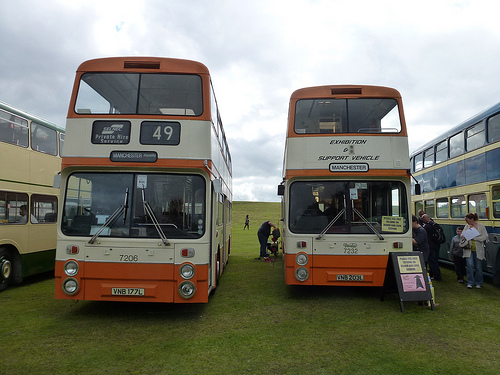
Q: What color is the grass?
A: Green.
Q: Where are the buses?
A: On the grass.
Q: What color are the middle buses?
A: Orange and white.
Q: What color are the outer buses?
A: White and black.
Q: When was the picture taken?
A: Daytime.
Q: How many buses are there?
A: Four.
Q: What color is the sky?
A: Gray.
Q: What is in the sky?
A: Clouds.